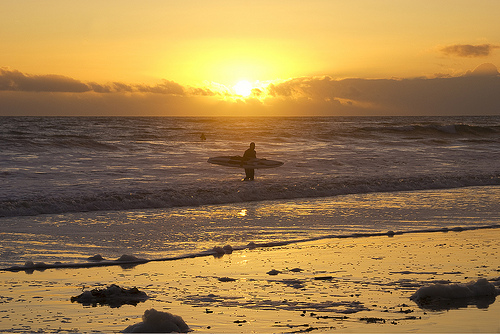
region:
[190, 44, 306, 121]
the sun on the horizon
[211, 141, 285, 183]
surfer with surfboard standing in the ocean tides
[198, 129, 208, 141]
small figure off in the distance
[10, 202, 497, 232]
thin layer of water meeting the sand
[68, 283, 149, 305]
cluster of seaweed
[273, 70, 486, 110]
clouds rolling over the sky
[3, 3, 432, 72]
a clear and orange sky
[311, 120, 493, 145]
waves of water rolling in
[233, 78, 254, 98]
actual ball of sun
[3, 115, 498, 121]
calm water off in the distance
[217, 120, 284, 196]
person in a body of water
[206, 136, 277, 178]
person carrying a surfboard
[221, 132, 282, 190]
person with a surfbaord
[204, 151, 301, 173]
surfboard is being carried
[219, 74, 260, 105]
sun is setting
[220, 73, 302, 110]
sunset can be seen through the clouds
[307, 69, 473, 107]
clouds in the sky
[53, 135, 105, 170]
body of water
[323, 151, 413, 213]
small wave hitting the beach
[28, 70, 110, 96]
clouds in the sky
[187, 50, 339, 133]
a beautiful view of sun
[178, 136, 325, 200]
a man in water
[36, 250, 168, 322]
a small rock in water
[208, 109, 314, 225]
a man walking in water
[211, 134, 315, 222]
a man running in water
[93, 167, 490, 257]
riddles in the water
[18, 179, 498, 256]
a normal flow of water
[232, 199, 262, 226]
sun shine in water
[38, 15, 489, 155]
a beautiful view of sun set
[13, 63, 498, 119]
a super view of clouds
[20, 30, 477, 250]
a sunset over a beach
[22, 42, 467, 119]
the sun is fading behind the clouds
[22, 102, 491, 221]
the water is moving through the area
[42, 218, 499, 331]
the beach area is muddy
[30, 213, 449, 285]
tides coming onto the beach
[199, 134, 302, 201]
a surfboarder in the water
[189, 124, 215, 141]
a surfboarder in the background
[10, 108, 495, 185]
the waves in the water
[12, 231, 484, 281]
foam from the water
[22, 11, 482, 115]
the sunset sky is orange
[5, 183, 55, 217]
Ripples in the water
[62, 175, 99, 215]
Ripples in the water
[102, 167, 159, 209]
Ripples in the water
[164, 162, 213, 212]
Ripples in the water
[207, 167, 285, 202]
Ripples in the water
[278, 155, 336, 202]
Ripples in the water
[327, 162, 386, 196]
Ripples in the water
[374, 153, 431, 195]
Ripples in the water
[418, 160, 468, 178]
Ripples in the water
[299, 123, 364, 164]
Ripples in the water